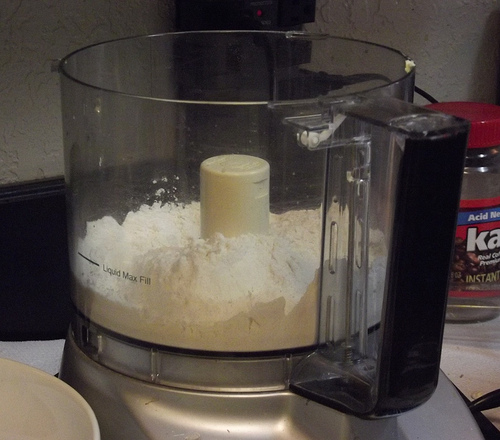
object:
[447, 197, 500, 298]
label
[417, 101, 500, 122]
top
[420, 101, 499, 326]
bottle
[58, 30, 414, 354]
mixer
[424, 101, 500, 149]
lid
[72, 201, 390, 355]
flour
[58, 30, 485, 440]
blender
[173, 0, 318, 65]
wall socket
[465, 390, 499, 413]
cord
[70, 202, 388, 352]
powder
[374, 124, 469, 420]
handle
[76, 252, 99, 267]
black line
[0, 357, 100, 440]
bowl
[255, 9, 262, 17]
button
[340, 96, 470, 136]
top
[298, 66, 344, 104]
plug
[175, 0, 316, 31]
surface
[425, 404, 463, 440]
cording